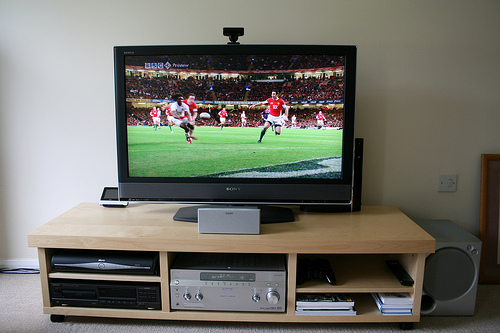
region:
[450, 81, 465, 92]
part of a wall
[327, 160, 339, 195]
part of a screen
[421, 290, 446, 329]
part of a speaker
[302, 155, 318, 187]
edge of a screen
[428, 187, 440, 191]
part of a switch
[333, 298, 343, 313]
part of a book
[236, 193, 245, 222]
part of a speaker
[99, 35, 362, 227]
Tv on the stand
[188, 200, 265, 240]
Speaker in front of tv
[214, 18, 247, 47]
Sensor on top of tv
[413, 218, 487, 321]
Speaker on the floor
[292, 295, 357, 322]
Stack of game on shelf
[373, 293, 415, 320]
Stack of games on shelf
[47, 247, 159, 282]
Black box on shelf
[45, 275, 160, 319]
Black console on the shelf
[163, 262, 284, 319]
Stereo system on the shelf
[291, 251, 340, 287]
Game remote on shelf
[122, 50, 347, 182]
a soccer game on a television screen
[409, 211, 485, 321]
gray speaker box on the floor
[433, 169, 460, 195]
outlet on the wall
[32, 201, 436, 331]
low laying entertainment center stand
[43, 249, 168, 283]
a dvd player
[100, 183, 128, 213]
cellphone on the entertainment center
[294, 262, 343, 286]
play station game controller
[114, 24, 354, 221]
a black flat screen television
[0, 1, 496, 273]
a white wall behind the television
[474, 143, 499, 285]
brown frame laying against the wall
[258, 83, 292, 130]
player on tv screen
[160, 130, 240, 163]
well maintained green graSS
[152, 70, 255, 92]
stands filled with people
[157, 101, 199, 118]
player wearing white jersey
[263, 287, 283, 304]
large silver knob on receiver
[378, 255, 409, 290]
thin black remote under counter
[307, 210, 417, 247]
light brown table top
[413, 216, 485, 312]
silver speaker on the wall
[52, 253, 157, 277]
shiny black DVD player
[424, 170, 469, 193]
small white socket on wall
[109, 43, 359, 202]
Wide screen television on entertainment center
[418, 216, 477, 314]
Auxiliary audio speaker on floor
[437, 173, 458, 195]
Electric power outlet on wall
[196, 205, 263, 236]
Center auxiliary audio speaker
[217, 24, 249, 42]
Game system motion capture camera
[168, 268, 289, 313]
Receiver on entertainment center shelf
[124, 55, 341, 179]
Soccer match on television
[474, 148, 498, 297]
Framed picture on floor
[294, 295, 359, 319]
Plastic white DVD cases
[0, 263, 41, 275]
Electric power cords on floor